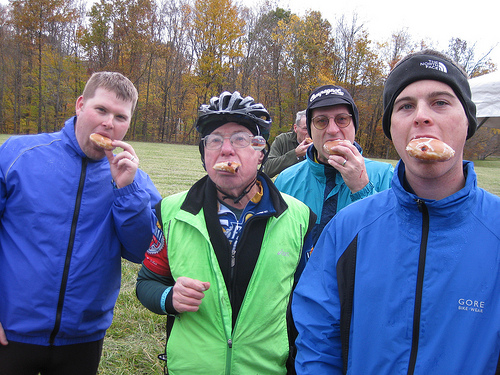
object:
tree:
[147, 0, 189, 137]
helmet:
[192, 90, 274, 143]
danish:
[383, 139, 474, 172]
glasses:
[198, 129, 268, 158]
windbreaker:
[0, 116, 165, 345]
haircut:
[74, 63, 144, 102]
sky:
[0, 0, 500, 60]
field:
[0, 139, 500, 375]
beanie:
[371, 52, 473, 121]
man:
[284, 49, 500, 375]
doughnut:
[209, 159, 245, 180]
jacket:
[292, 154, 499, 375]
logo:
[449, 290, 493, 315]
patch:
[136, 228, 178, 276]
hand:
[163, 272, 214, 313]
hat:
[301, 82, 361, 134]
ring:
[339, 157, 349, 167]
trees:
[257, 8, 331, 144]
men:
[0, 64, 171, 375]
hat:
[379, 50, 479, 142]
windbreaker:
[275, 156, 396, 224]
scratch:
[355, 168, 369, 181]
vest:
[148, 187, 325, 342]